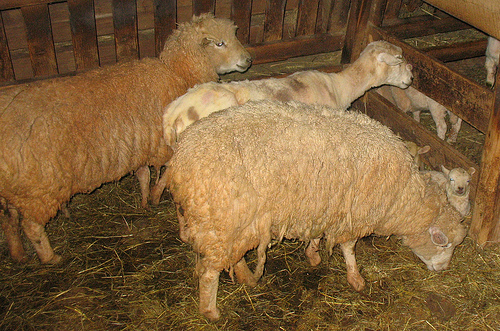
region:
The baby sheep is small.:
[417, 158, 480, 213]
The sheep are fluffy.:
[168, 103, 496, 323]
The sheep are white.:
[162, 99, 474, 327]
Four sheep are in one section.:
[7, 13, 489, 323]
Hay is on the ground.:
[7, 152, 499, 328]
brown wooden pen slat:
[17, 5, 59, 76]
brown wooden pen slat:
[65, 0, 101, 69]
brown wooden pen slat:
[111, 2, 139, 62]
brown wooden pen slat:
[151, 0, 178, 56]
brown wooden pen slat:
[191, 0, 218, 16]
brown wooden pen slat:
[230, 3, 251, 44]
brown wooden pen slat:
[263, 0, 285, 42]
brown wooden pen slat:
[295, 2, 315, 39]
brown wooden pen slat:
[370, 29, 487, 131]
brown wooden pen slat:
[346, 90, 479, 199]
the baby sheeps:
[408, 138, 478, 215]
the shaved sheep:
[158, 27, 415, 148]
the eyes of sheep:
[212, 36, 472, 187]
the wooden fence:
[348, 0, 496, 255]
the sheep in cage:
[1, 9, 497, 316]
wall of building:
[3, 0, 350, 86]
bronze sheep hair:
[3, 11, 253, 267]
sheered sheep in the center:
[158, 33, 421, 145]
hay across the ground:
[8, 178, 498, 330]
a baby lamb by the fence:
[416, 156, 479, 222]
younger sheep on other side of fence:
[371, 73, 460, 150]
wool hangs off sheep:
[251, 218, 346, 290]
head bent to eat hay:
[378, 183, 471, 290]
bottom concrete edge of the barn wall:
[261, 16, 496, 87]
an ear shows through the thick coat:
[429, 228, 449, 258]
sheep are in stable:
[41, 17, 494, 317]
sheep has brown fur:
[31, 23, 236, 148]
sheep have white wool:
[191, 72, 491, 278]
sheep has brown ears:
[394, 207, 462, 260]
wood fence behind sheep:
[6, 1, 211, 71]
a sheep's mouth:
[218, 36, 259, 77]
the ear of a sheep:
[411, 225, 456, 252]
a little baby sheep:
[429, 155, 478, 217]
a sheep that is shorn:
[150, 41, 412, 106]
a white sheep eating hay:
[176, 114, 475, 319]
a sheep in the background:
[156, 80, 483, 330]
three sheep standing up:
[26, 15, 497, 296]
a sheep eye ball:
[199, 26, 266, 96]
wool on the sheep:
[138, 97, 485, 329]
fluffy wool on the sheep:
[152, 90, 477, 310]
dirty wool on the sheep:
[6, 33, 236, 263]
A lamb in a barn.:
[138, 32, 435, 158]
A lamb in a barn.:
[0, 11, 256, 280]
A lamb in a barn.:
[422, 158, 479, 222]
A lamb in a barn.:
[369, 58, 476, 142]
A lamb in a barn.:
[479, 26, 499, 79]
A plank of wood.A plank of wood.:
[344, 21, 499, 126]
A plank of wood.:
[346, 84, 481, 208]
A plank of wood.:
[230, 2, 255, 50]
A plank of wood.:
[263, 3, 286, 48]